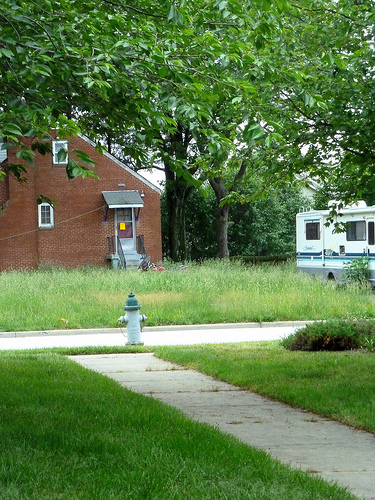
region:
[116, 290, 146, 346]
fire hydrant next to road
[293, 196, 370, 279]
a rv is parked in the grass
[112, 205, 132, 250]
door into the brick building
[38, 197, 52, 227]
window into the building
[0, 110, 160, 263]
red brick 2 story building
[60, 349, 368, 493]
sidewalk to the road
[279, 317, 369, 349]
low lying green bush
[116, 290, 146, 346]
white and green fire hydrant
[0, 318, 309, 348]
narrow road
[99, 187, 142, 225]
cover over door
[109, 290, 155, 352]
Blue fire hydrant on curb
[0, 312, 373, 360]
Street running left to right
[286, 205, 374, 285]
Blue and white motor home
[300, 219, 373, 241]
Windows on motor home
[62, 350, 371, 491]
Sidewalk running to street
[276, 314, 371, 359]
Green and brown bush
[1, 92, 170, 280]
Red brick building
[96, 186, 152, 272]
Door of red brick building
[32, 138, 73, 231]
Windows of red brick building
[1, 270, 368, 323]
Tall Green Grass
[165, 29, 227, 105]
Green leaves on the tree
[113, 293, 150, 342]
Green fire hydrant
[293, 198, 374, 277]
White motor home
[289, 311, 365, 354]
Green bush beside the street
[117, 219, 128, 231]
Yellow note on door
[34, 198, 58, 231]
White window on brick house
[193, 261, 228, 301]
Tall weeds in yard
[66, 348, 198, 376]
Sidewalk with weeds growing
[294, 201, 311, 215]
Metal ladder on motorhome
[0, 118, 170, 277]
Brick house with white windows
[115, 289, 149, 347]
a green fire hydrant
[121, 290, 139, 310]
The top of the hydrant is darker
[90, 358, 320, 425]
Patches of grass in the sidewalk lines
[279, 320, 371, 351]
A small shrub in the yard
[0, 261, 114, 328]
Tall grass in the yard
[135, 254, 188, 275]
A red motorcycle in tall grass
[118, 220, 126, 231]
a yellow piece of paper on the door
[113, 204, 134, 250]
The white front screen door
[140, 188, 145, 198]
a porch light on the brick wall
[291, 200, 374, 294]
A white RV with blue lines on it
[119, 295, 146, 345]
a green and grey fire hydrant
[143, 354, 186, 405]
a white walk way path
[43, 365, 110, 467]
a green grass area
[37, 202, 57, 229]
it is a white window in a building made of bricks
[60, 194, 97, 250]
a brown building made of bricks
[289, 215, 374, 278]
a rv is parked outside of the building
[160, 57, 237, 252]
trees are beside the building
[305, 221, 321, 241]
a window in the rv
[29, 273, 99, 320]
a bunch of tall weeds in front of the building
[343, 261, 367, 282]
leaves are growing on the rv